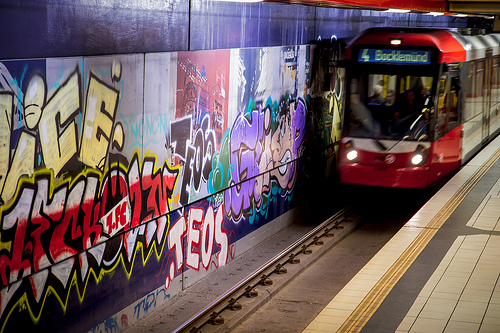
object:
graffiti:
[0, 41, 353, 332]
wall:
[0, 0, 470, 333]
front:
[337, 26, 467, 190]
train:
[336, 24, 500, 190]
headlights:
[346, 149, 359, 161]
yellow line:
[335, 212, 447, 333]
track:
[170, 207, 385, 333]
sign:
[356, 47, 430, 66]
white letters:
[165, 215, 187, 273]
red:
[190, 205, 205, 211]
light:
[389, 39, 402, 45]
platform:
[120, 132, 500, 333]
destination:
[360, 48, 428, 63]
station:
[1, 0, 500, 330]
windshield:
[343, 67, 440, 143]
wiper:
[385, 95, 433, 153]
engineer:
[394, 88, 425, 122]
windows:
[463, 57, 486, 124]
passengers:
[367, 84, 391, 105]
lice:
[0, 63, 123, 207]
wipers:
[348, 107, 388, 151]